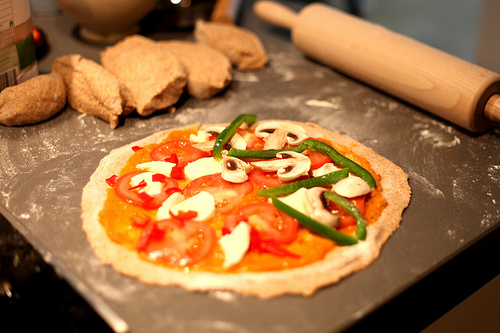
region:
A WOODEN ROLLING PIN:
[243, 2, 499, 138]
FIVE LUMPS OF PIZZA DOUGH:
[3, 22, 275, 135]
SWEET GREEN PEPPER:
[258, 166, 381, 245]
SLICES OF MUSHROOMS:
[184, 116, 314, 186]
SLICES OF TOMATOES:
[172, 199, 301, 264]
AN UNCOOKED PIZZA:
[78, 110, 410, 300]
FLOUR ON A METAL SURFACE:
[4, 124, 80, 239]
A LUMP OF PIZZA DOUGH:
[2, 66, 67, 131]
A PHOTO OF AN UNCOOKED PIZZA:
[78, 107, 420, 302]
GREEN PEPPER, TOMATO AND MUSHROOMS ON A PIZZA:
[96, 110, 392, 272]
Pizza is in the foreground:
[58, 106, 443, 308]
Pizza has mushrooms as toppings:
[190, 102, 358, 234]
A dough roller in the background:
[250, 2, 497, 152]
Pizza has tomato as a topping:
[115, 145, 295, 270]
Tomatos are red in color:
[105, 130, 303, 276]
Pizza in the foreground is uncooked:
[65, 101, 435, 293]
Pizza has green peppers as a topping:
[203, 98, 383, 266]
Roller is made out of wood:
[252, 2, 497, 147]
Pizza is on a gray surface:
[20, 97, 453, 329]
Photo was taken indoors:
[2, 5, 495, 332]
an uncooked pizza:
[36, 41, 446, 331]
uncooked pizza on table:
[75, 95, 421, 307]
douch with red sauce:
[41, 86, 393, 313]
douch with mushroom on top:
[94, 87, 439, 299]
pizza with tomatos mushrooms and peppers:
[79, 70, 368, 295]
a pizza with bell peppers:
[87, 110, 417, 317]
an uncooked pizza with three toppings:
[69, 116, 435, 296]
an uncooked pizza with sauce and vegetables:
[36, 107, 443, 302]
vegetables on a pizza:
[82, 100, 444, 324]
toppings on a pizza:
[62, 116, 427, 327]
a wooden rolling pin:
[270, 3, 496, 138]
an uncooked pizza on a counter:
[83, 106, 398, 307]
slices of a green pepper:
[221, 105, 286, 163]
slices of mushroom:
[211, 150, 317, 176]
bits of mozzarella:
[158, 188, 218, 228]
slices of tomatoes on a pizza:
[110, 190, 152, 245]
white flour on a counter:
[2, 130, 67, 242]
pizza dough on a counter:
[10, 20, 270, 123]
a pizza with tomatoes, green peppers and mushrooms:
[95, 100, 415, 302]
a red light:
[24, 24, 47, 48]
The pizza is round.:
[87, 119, 415, 287]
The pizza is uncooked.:
[54, 114, 419, 311]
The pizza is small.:
[73, 107, 418, 301]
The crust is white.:
[368, 147, 436, 239]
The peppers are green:
[261, 167, 353, 195]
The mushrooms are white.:
[250, 146, 308, 176]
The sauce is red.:
[223, 194, 260, 218]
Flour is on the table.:
[8, 140, 71, 210]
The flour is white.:
[13, 148, 70, 208]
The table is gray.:
[416, 210, 450, 253]